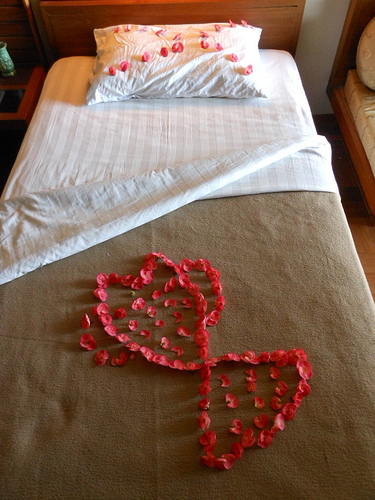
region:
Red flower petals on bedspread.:
[76, 250, 317, 466]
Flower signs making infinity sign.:
[67, 250, 315, 471]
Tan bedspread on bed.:
[11, 369, 193, 498]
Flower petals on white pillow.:
[92, 19, 263, 99]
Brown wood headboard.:
[44, 0, 307, 46]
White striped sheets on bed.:
[36, 93, 319, 191]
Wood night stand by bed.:
[2, 1, 44, 130]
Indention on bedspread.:
[18, 371, 93, 453]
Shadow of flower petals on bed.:
[163, 377, 205, 482]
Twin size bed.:
[12, 0, 350, 488]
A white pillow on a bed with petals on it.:
[85, 20, 263, 103]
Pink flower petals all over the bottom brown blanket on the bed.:
[80, 250, 313, 469]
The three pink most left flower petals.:
[81, 313, 109, 366]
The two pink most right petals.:
[288, 346, 314, 379]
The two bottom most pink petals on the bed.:
[200, 451, 236, 470]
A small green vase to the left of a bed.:
[0, 41, 17, 74]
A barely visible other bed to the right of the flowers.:
[325, 1, 374, 229]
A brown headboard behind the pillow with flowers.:
[39, 1, 307, 66]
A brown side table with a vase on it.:
[0, 63, 46, 128]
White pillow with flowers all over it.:
[85, 21, 269, 106]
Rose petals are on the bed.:
[66, 256, 316, 472]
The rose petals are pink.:
[70, 248, 315, 468]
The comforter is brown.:
[14, 210, 374, 495]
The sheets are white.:
[29, 56, 332, 196]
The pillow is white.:
[90, 20, 262, 100]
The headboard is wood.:
[35, 4, 294, 62]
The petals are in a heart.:
[64, 242, 317, 474]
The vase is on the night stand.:
[0, 46, 16, 73]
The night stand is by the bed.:
[0, 61, 43, 126]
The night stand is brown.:
[1, 66, 43, 126]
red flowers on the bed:
[72, 263, 303, 453]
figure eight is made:
[83, 252, 284, 459]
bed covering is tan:
[0, 257, 372, 499]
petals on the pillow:
[99, 29, 274, 106]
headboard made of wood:
[28, 0, 296, 51]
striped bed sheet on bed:
[43, 98, 312, 194]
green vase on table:
[1, 59, 18, 79]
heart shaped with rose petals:
[93, 262, 209, 371]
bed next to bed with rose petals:
[326, 5, 374, 185]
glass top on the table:
[0, 67, 23, 113]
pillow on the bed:
[83, 21, 265, 112]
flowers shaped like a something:
[74, 252, 320, 465]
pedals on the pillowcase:
[93, 21, 261, 87]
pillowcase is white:
[105, 18, 261, 111]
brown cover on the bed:
[134, 195, 373, 226]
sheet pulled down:
[1, 129, 355, 250]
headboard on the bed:
[17, 2, 314, 55]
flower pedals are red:
[72, 217, 321, 496]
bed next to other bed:
[326, 31, 373, 180]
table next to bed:
[3, 38, 39, 104]